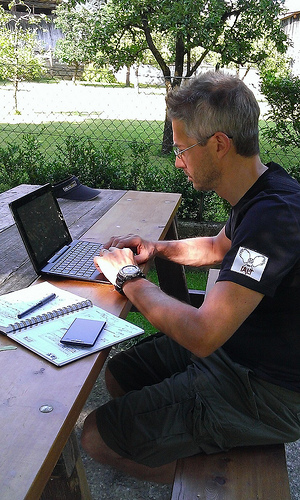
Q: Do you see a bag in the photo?
A: No, there are no bags.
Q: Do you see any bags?
A: No, there are no bags.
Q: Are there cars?
A: No, there are no cars.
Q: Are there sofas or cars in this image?
A: No, there are no cars or sofas.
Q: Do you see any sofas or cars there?
A: No, there are no cars or sofas.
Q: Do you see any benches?
A: Yes, there is a bench.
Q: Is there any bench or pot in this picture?
A: Yes, there is a bench.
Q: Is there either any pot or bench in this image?
A: Yes, there is a bench.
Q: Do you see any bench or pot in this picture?
A: Yes, there is a bench.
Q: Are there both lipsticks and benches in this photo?
A: No, there is a bench but no lipsticks.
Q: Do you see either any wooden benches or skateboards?
A: Yes, there is a wood bench.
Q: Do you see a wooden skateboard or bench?
A: Yes, there is a wood bench.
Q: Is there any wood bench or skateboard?
A: Yes, there is a wood bench.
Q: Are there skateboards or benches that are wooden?
A: Yes, the bench is wooden.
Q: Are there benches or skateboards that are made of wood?
A: Yes, the bench is made of wood.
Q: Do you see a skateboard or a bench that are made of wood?
A: Yes, the bench is made of wood.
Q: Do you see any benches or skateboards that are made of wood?
A: Yes, the bench is made of wood.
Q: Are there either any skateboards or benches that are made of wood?
A: Yes, the bench is made of wood.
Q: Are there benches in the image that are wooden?
A: Yes, there is a wood bench.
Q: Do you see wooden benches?
A: Yes, there is a wood bench.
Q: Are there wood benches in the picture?
A: Yes, there is a wood bench.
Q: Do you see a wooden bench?
A: Yes, there is a wood bench.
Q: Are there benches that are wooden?
A: Yes, there is a bench that is wooden.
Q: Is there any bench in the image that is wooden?
A: Yes, there is a bench that is wooden.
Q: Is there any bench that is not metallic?
A: Yes, there is a wooden bench.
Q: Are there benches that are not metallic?
A: Yes, there is a wooden bench.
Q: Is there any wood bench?
A: Yes, there is a bench that is made of wood.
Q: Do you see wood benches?
A: Yes, there is a bench that is made of wood.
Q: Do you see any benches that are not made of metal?
A: Yes, there is a bench that is made of wood.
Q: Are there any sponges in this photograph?
A: No, there are no sponges.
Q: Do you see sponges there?
A: No, there are no sponges.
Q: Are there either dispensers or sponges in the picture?
A: No, there are no sponges or dispensers.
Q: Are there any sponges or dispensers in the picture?
A: No, there are no sponges or dispensers.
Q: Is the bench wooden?
A: Yes, the bench is wooden.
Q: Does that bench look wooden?
A: Yes, the bench is wooden.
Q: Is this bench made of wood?
A: Yes, the bench is made of wood.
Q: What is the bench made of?
A: The bench is made of wood.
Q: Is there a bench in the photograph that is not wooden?
A: No, there is a bench but it is wooden.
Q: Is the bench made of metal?
A: No, the bench is made of wood.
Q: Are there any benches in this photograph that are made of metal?
A: No, there is a bench but it is made of wood.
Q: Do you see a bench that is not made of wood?
A: No, there is a bench but it is made of wood.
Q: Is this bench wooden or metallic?
A: The bench is wooden.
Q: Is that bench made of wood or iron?
A: The bench is made of wood.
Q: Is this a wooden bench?
A: Yes, this is a wooden bench.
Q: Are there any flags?
A: No, there are no flags.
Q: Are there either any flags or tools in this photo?
A: No, there are no flags or tools.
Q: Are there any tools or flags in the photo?
A: No, there are no flags or tools.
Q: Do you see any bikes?
A: No, there are no bikes.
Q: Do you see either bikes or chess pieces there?
A: No, there are no bikes or chess pieces.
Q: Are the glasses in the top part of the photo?
A: Yes, the glasses are in the top of the image.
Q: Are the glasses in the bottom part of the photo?
A: No, the glasses are in the top of the image.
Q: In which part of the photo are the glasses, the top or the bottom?
A: The glasses are in the top of the image.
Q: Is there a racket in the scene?
A: No, there are no rackets.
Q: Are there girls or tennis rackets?
A: No, there are no tennis rackets or girls.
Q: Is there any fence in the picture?
A: Yes, there is a fence.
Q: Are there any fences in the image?
A: Yes, there is a fence.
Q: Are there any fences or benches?
A: Yes, there is a fence.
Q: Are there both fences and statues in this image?
A: No, there is a fence but no statues.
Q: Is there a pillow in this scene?
A: No, there are no pillows.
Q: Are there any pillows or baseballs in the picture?
A: No, there are no pillows or baseballs.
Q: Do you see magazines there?
A: No, there are no magazines.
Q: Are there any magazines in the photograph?
A: No, there are no magazines.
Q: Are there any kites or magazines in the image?
A: No, there are no magazines or kites.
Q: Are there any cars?
A: No, there are no cars.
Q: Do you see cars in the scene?
A: No, there are no cars.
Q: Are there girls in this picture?
A: No, there are no girls.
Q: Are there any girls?
A: No, there are no girls.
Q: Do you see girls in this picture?
A: No, there are no girls.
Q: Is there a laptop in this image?
A: Yes, there is a laptop.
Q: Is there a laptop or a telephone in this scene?
A: Yes, there is a laptop.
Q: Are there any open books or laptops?
A: Yes, there is an open laptop.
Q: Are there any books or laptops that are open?
A: Yes, the laptop is open.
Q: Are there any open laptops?
A: Yes, there is an open laptop.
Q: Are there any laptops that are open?
A: Yes, there is a laptop that is open.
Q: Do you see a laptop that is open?
A: Yes, there is a laptop that is open.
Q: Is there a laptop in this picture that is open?
A: Yes, there is a laptop that is open.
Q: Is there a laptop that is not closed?
A: Yes, there is a open laptop.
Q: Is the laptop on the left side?
A: Yes, the laptop is on the left of the image.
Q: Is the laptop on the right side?
A: No, the laptop is on the left of the image.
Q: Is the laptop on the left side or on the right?
A: The laptop is on the left of the image.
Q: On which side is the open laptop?
A: The laptop is on the left of the image.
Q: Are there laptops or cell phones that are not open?
A: No, there is a laptop but it is open.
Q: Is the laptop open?
A: Yes, the laptop is open.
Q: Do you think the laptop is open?
A: Yes, the laptop is open.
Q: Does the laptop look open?
A: Yes, the laptop is open.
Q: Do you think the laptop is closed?
A: No, the laptop is open.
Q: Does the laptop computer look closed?
A: No, the laptop computer is open.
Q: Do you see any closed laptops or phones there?
A: No, there is a laptop but it is open.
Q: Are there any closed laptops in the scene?
A: No, there is a laptop but it is open.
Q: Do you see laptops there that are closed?
A: No, there is a laptop but it is open.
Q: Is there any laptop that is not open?
A: No, there is a laptop but it is open.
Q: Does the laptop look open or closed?
A: The laptop is open.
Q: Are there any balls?
A: No, there are no balls.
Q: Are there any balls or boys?
A: No, there are no balls or boys.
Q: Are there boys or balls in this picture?
A: No, there are no balls or boys.